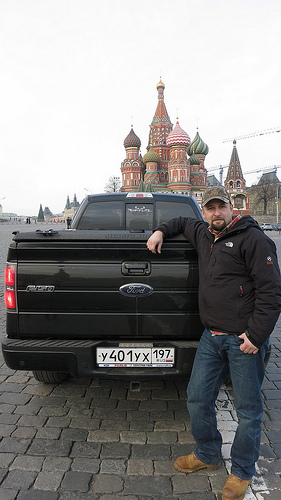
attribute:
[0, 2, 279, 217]
sky — white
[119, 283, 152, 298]
logo — blue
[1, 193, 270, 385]
truck — black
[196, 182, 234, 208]
cap — camoflage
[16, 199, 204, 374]
truck — parked, black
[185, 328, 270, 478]
jeans — blue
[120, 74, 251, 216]
building — large, colorful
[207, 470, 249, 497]
shoes — brown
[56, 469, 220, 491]
cobblestone — Gray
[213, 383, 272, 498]
line — white